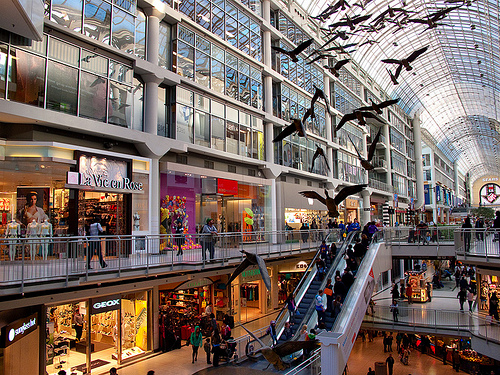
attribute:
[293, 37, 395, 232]
models — suspended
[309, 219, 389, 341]
people — standing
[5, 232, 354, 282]
floor — upper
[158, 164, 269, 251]
window — orange, green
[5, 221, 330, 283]
rail — silver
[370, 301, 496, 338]
railings — safety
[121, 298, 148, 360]
lights — on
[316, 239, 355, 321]
people — riding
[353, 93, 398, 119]
bird — flying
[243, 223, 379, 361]
escalators — gray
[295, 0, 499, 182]
roof — grey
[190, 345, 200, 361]
pants — black, skinny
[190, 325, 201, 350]
hoodie — green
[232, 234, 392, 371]
walkway — elevated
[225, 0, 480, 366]
birds — brown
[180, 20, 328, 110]
sky — blue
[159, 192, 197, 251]
display — colorful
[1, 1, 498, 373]
mall — large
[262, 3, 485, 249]
mobile — hanging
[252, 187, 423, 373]
escalator — moving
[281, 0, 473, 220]
geese — canadian